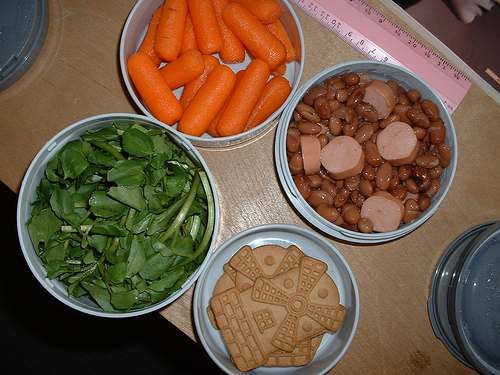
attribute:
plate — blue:
[191, 222, 361, 373]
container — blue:
[10, 108, 233, 325]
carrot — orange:
[214, 55, 269, 139]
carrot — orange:
[244, 73, 294, 132]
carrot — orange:
[128, 48, 185, 124]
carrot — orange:
[158, 45, 206, 89]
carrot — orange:
[219, 0, 287, 69]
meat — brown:
[319, 135, 361, 177]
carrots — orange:
[127, 0, 300, 138]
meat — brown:
[373, 121, 421, 163]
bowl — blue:
[274, 55, 466, 257]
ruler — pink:
[306, 2, 473, 113]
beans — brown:
[285, 64, 451, 226]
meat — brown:
[316, 135, 365, 178]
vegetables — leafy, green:
[28, 129, 206, 302]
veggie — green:
[44, 149, 189, 293]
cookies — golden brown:
[207, 239, 332, 356]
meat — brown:
[368, 121, 422, 163]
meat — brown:
[311, 123, 373, 188]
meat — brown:
[287, 130, 327, 185]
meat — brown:
[344, 181, 411, 236]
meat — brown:
[349, 76, 405, 120]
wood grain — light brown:
[362, 257, 419, 334]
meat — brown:
[367, 81, 392, 116]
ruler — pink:
[290, 4, 473, 118]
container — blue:
[428, 219, 498, 373]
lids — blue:
[421, 223, 499, 372]